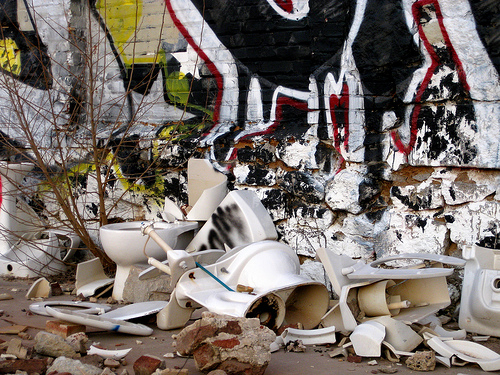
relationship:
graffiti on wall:
[0, 0, 499, 312] [130, 7, 497, 199]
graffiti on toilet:
[197, 201, 250, 251] [125, 198, 414, 338]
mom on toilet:
[198, 204, 247, 254] [125, 198, 414, 338]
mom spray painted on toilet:
[198, 204, 247, 254] [125, 198, 414, 338]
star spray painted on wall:
[116, 60, 207, 160] [130, 7, 497, 199]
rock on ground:
[38, 324, 114, 364] [33, 284, 477, 374]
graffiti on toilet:
[53, 127, 467, 355] [125, 198, 414, 338]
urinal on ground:
[87, 190, 453, 340] [33, 284, 477, 374]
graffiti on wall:
[82, 183, 478, 347] [130, 7, 497, 199]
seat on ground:
[91, 175, 411, 373] [33, 284, 477, 374]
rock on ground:
[38, 326, 88, 366] [33, 284, 477, 374]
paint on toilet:
[90, 182, 340, 327] [125, 198, 414, 338]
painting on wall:
[14, 9, 497, 234] [130, 7, 497, 199]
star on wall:
[165, 26, 219, 89] [6, 5, 482, 203]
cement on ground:
[230, 351, 342, 353] [33, 284, 477, 374]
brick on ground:
[59, 335, 200, 373] [33, 284, 477, 374]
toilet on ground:
[125, 198, 414, 338] [104, 342, 390, 371]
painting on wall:
[14, 9, 497, 234] [4, 7, 484, 180]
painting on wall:
[14, 9, 476, 174] [130, 7, 497, 199]